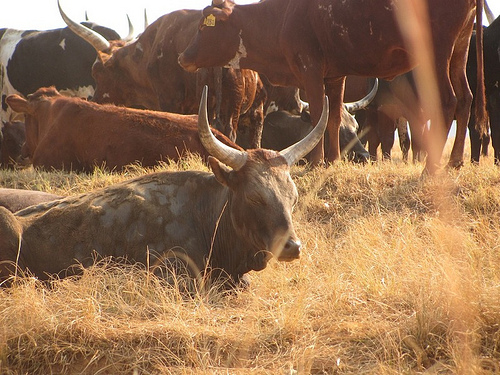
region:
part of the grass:
[393, 289, 423, 306]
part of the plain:
[291, 345, 310, 367]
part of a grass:
[286, 314, 301, 326]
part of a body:
[96, 203, 127, 247]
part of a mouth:
[273, 243, 283, 258]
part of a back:
[201, 161, 216, 185]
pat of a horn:
[198, 128, 216, 153]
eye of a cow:
[254, 198, 259, 203]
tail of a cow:
[118, 248, 131, 269]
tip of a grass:
[234, 328, 273, 347]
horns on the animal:
[196, 93, 235, 154]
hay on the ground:
[351, 227, 490, 357]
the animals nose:
[280, 237, 301, 252]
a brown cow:
[179, 9, 463, 87]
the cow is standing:
[173, 8, 493, 98]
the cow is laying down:
[10, 77, 325, 287]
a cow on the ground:
[13, 85, 184, 175]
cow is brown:
[9, 87, 168, 165]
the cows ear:
[199, 150, 226, 187]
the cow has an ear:
[2, 90, 37, 120]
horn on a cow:
[187, 71, 254, 176]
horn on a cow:
[283, 95, 340, 167]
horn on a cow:
[53, 0, 115, 55]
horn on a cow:
[340, 73, 385, 117]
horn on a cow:
[292, 81, 314, 118]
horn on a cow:
[118, 9, 141, 45]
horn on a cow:
[80, 7, 90, 23]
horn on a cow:
[139, 3, 154, 33]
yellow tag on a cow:
[200, 7, 220, 31]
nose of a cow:
[268, 225, 307, 265]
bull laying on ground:
[4, 150, 384, 307]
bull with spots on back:
[1, 122, 339, 274]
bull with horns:
[2, 91, 402, 359]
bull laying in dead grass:
[0, 133, 437, 340]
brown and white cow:
[208, 0, 482, 155]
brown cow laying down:
[12, 83, 244, 179]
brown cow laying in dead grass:
[1, 101, 259, 173]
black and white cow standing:
[7, 7, 108, 110]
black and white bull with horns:
[225, 71, 376, 171]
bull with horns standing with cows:
[63, 10, 144, 99]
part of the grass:
[390, 248, 414, 275]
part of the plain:
[264, 298, 282, 331]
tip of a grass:
[237, 323, 257, 345]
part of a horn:
[204, 143, 211, 145]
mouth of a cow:
[285, 230, 294, 243]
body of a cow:
[121, 223, 136, 235]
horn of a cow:
[205, 138, 220, 163]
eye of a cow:
[251, 185, 263, 231]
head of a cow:
[262, 205, 271, 212]